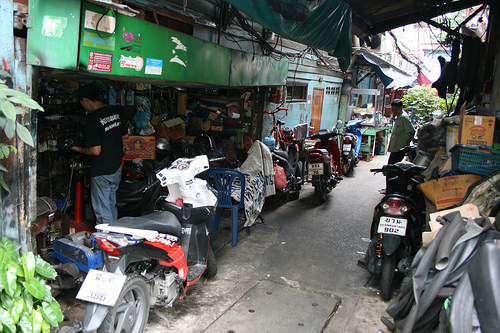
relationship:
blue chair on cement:
[194, 168, 250, 247] [51, 147, 416, 333]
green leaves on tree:
[403, 85, 438, 115] [400, 82, 440, 137]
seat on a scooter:
[121, 206, 189, 231] [69, 152, 234, 329]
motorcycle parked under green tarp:
[365, 161, 428, 302] [228, 0, 355, 74]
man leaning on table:
[389, 99, 416, 166] [406, 140, 441, 175]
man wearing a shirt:
[73, 90, 136, 215] [64, 103, 140, 193]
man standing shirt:
[389, 99, 416, 166] [368, 111, 425, 143]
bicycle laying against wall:
[260, 103, 300, 153] [261, 67, 376, 149]